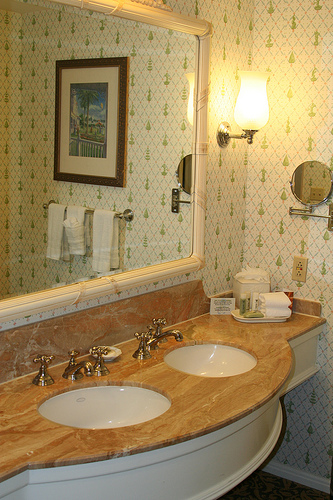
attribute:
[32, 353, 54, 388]
fixture — silver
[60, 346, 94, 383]
fixture — silver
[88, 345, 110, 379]
fixture — silver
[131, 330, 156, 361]
fixture — silver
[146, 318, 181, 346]
fixture — silver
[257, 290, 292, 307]
towel — white, folded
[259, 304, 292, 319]
towel — white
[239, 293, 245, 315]
toiletry — single, serving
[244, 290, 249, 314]
toiletry — serving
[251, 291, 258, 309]
toiletry — single, serving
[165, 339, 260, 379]
sink — white, ceramic, bathroom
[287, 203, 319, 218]
hinge — vanity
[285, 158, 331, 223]
mirror — round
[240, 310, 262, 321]
soap — green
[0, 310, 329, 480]
countertop — marble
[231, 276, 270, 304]
tissueholder — white, plastic, tissue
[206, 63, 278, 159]
light — white, silver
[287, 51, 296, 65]
tree — green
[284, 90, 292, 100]
tree — green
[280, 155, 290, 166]
tree — green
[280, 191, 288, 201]
tree — green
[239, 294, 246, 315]
bottle — plastic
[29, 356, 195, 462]
sink — bathroom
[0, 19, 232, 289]
mirror — rectangular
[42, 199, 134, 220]
towel bar — silver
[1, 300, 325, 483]
counter — top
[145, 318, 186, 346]
faucet — silver, metal, sink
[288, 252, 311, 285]
outlet — electrical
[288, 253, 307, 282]
outlet — tan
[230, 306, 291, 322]
tray — white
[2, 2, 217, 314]
mirror — framed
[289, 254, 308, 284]
outlet — beige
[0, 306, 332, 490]
counter top — brown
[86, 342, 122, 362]
soap dish — small, round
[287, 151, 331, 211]
mirror — small, circular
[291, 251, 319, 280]
outlet — power, wall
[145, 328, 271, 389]
white sink — round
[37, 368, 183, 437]
white sink — round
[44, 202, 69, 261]
towel — white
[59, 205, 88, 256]
towel — white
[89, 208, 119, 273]
towel — white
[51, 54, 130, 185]
frame — brown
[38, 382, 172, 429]
sink — white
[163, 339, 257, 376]
sink — white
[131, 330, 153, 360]
handle — silver, metal, sink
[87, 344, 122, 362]
soap dish — white